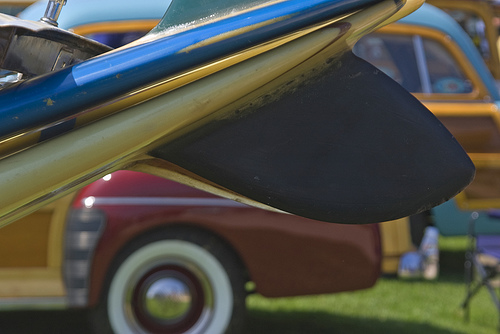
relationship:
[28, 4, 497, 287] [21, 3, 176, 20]
car has roof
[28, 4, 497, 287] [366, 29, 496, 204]
car has door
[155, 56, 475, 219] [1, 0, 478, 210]
fin on surfboard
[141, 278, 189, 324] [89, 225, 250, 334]
hubcap on tire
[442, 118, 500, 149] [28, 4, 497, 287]
panel on car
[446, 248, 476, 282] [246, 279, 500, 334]
shadow on grass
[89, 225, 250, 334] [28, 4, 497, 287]
tire on car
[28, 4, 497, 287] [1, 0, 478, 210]
car carrying surfboard